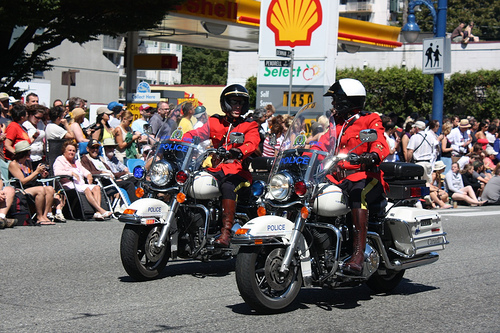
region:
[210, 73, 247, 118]
head of a person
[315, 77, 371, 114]
head of a person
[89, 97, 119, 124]
head of a person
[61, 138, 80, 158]
head of a person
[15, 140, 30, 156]
head of a person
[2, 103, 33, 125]
head of a person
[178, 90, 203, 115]
head of a person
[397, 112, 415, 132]
head of a person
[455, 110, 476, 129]
head of a person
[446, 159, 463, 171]
head of a person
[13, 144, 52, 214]
a person in the crowd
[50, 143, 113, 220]
a person in the crowd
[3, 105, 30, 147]
a person in the crowd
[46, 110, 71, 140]
a person in the crowd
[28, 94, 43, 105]
a person in the crowd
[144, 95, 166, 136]
a person in the crowd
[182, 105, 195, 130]
a person in the crowd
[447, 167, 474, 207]
a person in the crowd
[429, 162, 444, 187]
a person in the crowd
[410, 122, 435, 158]
a person in the crowd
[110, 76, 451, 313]
Two policemen and their motorcycles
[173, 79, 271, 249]
Policeman wearing a black helmet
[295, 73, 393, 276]
Policeman wearing a white helmet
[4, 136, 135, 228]
Three people sitting in lawn chairs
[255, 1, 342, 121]
Shell gas station sign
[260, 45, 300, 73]
Street signs behind the policemen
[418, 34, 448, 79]
White sign with black figures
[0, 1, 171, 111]
Large tree behind the people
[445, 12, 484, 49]
People sitting on the wall to the right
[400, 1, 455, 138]
Blue street lamp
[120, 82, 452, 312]
Two people on motorcycles.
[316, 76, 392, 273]
Person wearing a white helmet.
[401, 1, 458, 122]
Blue streetlight in a downtown area.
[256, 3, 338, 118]
White gas station sign.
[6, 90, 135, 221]
Crowd of people sitting in chairs.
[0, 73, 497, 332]
Crowd of people sitting along a street.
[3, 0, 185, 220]
Shade tree above a group of people.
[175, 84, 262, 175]
Person dressed in a red jacket.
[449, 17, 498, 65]
Two people sitting on a wall.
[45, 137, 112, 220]
Woman sitting in a chair.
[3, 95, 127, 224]
Many people sitting in a crowd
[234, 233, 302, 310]
Front wheel of a motorcycle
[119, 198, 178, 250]
Front fender of a white motorcycle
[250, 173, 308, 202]
Headlights on the front of a motorcycle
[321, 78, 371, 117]
A helmet on someone's head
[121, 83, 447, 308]
Two officers riding their bikes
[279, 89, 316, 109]
Numbers on a store's sign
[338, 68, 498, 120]
Green leaves on a bush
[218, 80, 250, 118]
A helmet worn by a man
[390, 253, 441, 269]
Muffler on a motorcycle